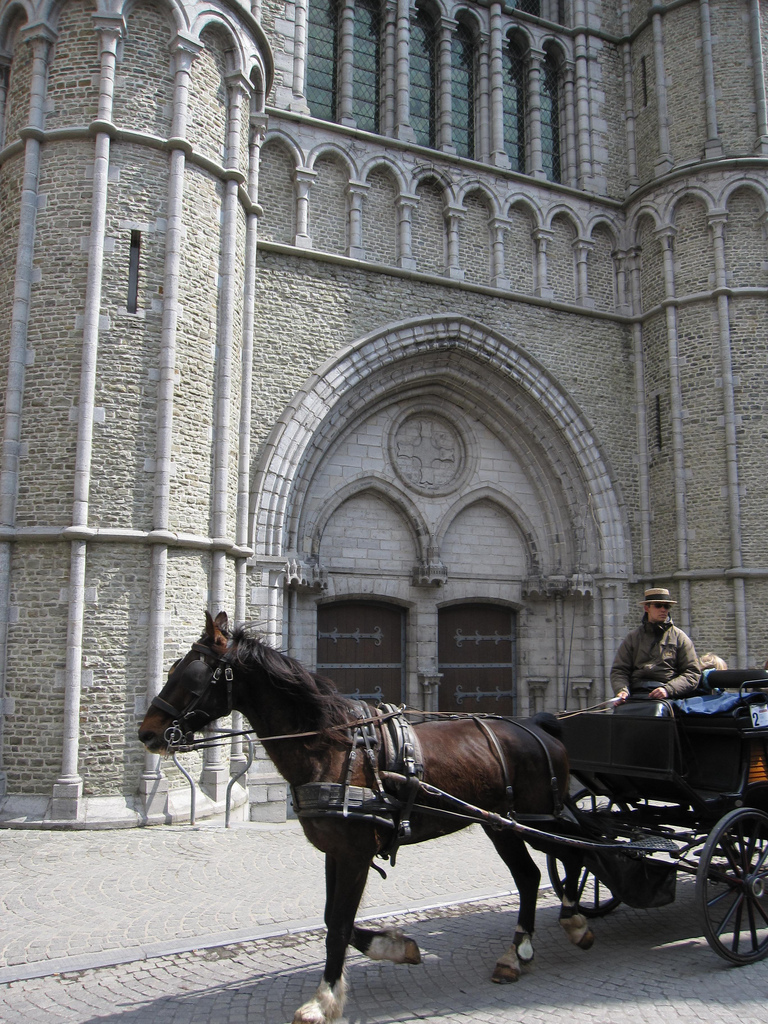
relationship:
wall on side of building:
[243, 242, 652, 822] [0, 5, 744, 834]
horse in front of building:
[139, 609, 597, 1021] [0, 5, 744, 834]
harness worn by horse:
[291, 703, 427, 860] [139, 609, 597, 1021]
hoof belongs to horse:
[395, 935, 421, 965] [139, 609, 597, 1021]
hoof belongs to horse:
[293, 989, 337, 1020] [139, 609, 597, 1021]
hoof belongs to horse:
[494, 954, 519, 981] [139, 609, 597, 1021]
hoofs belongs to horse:
[290, 903, 631, 1022] [139, 609, 597, 1021]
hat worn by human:
[640, 582, 677, 606] [604, 587, 705, 709]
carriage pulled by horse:
[384, 666, 764, 967] [139, 609, 597, 1021]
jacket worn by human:
[607, 610, 704, 701] [596, 578, 706, 703]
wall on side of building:
[86, 132, 175, 539] [4, 5, 732, 995]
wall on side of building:
[74, 532, 158, 817] [0, 5, 744, 834]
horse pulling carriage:
[139, 609, 597, 1021] [551, 665, 766, 966]